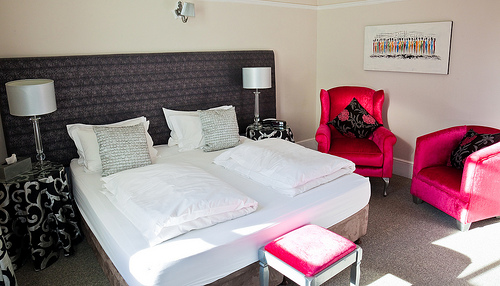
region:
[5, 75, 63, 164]
white cylindrical side table night lamp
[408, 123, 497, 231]
Red upholstered chair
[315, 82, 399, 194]
Red highback chair with a floral pillow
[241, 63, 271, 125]
Table lamp with white shade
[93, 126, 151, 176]
Square decorative pillow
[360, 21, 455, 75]
Multicolored wall picture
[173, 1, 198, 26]
Small wall lamp with shade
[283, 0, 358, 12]
White wall trim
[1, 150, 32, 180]
Box of klennex tissues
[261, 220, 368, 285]
Red cushioned ottoman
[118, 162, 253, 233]
Bright white bed linens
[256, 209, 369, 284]
wooden ottoman with red cushion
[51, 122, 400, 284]
king size bed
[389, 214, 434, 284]
beige carpet on floor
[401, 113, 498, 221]
small red upholstered chair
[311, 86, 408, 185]
red wing back arm chair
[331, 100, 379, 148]
floral decorative throw pillow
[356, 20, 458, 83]
picture hanging on the wall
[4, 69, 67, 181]
candlestick lamp on bedside table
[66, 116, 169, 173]
two pillows on bed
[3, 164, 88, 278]
black and silver tablecloth on bedside table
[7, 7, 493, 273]
a bedroom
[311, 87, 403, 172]
a pink armchair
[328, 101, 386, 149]
a black cushions with pink flowers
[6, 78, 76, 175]
a white lamp on a night table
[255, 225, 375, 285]
a small table at the foot of the bed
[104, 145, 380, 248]
white bedding on a bed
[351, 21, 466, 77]
a painting on the wall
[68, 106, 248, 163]
white and gray pillows on the bed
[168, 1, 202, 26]
a wall lamp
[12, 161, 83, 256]
a black and silvery tablecloth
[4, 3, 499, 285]
a large bedroom with lots of light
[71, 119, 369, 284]
a large white bed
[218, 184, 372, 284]
cushioned stool at foot of bed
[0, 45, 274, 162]
wide grey headboard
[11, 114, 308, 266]
small round tables on each side of bed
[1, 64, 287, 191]
tall table lamps on small tables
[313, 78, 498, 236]
two dark pink chairs against wall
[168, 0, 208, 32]
small shaded light on wall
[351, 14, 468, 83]
unframed colorful artwork on wall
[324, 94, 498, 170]
black and pink cushions on chairs